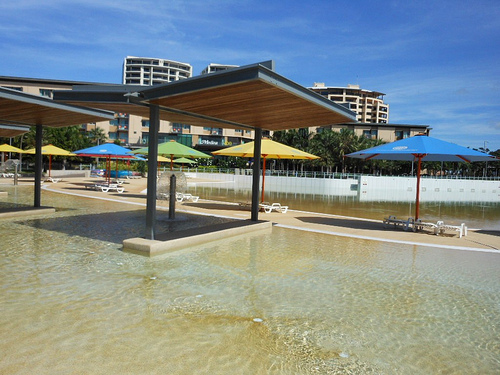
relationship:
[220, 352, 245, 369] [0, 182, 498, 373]
ripple in water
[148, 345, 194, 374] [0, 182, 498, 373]
ripple in water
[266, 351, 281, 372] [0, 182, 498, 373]
ripple in water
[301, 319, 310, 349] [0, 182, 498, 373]
ripple in water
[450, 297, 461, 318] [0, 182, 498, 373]
ripple in water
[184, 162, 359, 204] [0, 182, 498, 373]
reflection in water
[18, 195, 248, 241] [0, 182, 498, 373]
shadow on water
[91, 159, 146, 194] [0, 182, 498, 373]
chair by water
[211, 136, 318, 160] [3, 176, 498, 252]
umbrella on beach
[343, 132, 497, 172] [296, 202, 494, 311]
umbrella on beach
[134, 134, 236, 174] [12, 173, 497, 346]
umbrella on beach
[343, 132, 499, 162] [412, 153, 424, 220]
umbrella on pole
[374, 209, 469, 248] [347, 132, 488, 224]
chair under umbrella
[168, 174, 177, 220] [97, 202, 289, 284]
pole in water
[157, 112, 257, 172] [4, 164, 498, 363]
hotel next to beach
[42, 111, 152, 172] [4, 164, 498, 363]
hotel next to beach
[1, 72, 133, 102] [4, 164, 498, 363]
hotel next to beach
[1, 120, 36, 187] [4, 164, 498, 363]
hotel next to beach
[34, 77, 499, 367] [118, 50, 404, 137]
resorts behind hotel